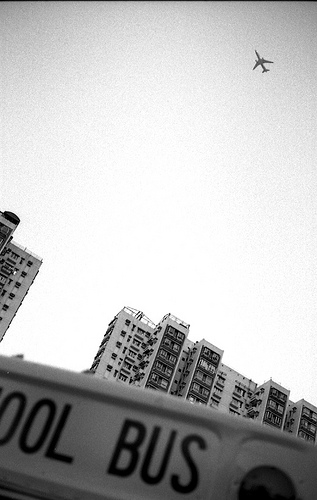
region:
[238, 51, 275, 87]
plane is in sky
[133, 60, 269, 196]
sky is grey and overcast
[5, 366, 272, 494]
school bus in foreground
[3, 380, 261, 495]
black letters on bus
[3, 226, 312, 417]
tall buildings behind bus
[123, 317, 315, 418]
many windows on buildings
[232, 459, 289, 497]
dark light on bus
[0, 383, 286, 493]
black letters on yellow background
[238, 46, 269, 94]
one plane in sky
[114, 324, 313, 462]
many balconies on buildings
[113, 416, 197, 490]
the word bus on a school bus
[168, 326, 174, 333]
the window of a building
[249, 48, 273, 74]
a plane in the skies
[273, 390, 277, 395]
an open window on a building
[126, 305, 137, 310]
roof bars on a building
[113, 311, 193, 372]
a storey building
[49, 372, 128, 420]
a school bus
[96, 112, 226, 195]
gray skies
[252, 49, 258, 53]
the nose of a plane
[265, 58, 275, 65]
the wing of a plane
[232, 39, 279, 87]
plane in the sky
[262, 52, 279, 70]
wing of the plane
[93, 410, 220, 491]
the word "bus"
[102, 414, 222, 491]
black word on bus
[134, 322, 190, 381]
windows on the building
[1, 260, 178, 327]
two buildings next to each other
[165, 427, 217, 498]
the letter s on bus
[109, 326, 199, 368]
light and dark building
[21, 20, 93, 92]
clear sky above building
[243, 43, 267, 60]
front of the plane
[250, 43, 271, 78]
one plane in sky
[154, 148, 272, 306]
sky is overcast and grey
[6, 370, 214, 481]
school bus under plane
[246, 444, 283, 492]
dark light on bus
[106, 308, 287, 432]
tall buildings behind bus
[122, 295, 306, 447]
light and dark exteriors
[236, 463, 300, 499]
circular light on school bus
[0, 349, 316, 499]
top of school bus in front of buildings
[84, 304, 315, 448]
light colored building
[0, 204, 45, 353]
light colored building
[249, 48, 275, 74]
jet airplane flying through the sky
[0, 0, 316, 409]
bright sky above city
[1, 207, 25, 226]
dark covered roof on top of building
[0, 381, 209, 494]
black lettering painted on school bus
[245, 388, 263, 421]
balconies hanging from building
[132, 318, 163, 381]
balconies hanging from building